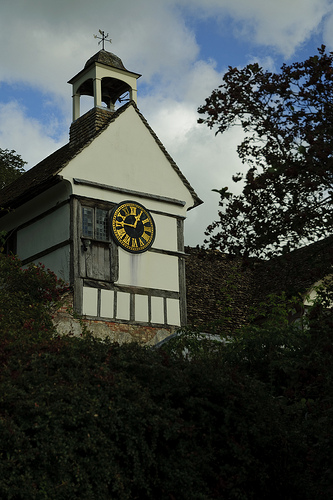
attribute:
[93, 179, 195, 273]
clock — showing 12:46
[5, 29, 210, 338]
tower — white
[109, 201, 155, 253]
clock — showing 12:46, round, black, gold, big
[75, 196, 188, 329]
wall — white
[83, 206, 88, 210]
pane — tiny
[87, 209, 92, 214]
pane — tiny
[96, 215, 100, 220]
pane — tiny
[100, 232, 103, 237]
pane — tiny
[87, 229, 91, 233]
pane — tiny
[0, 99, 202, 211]
roof — sloped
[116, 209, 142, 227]
hands — gold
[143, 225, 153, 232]
roman numeral — gold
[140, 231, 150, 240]
roman numeral — gold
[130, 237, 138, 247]
roman numeral — gold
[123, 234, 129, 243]
roman numeral — gold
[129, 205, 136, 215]
roman numeral — gold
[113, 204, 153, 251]
numbers — gold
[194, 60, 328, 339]
leaves — dark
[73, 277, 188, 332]
frame — Rectangular, wood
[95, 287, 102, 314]
slat — wood, vertical 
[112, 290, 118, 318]
slat — wood, vertical 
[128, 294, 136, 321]
slat — wood, vertical 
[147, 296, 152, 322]
slat — wood, vertical 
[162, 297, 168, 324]
slat — wood, vertical 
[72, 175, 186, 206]
slat — Horizontal , wooden